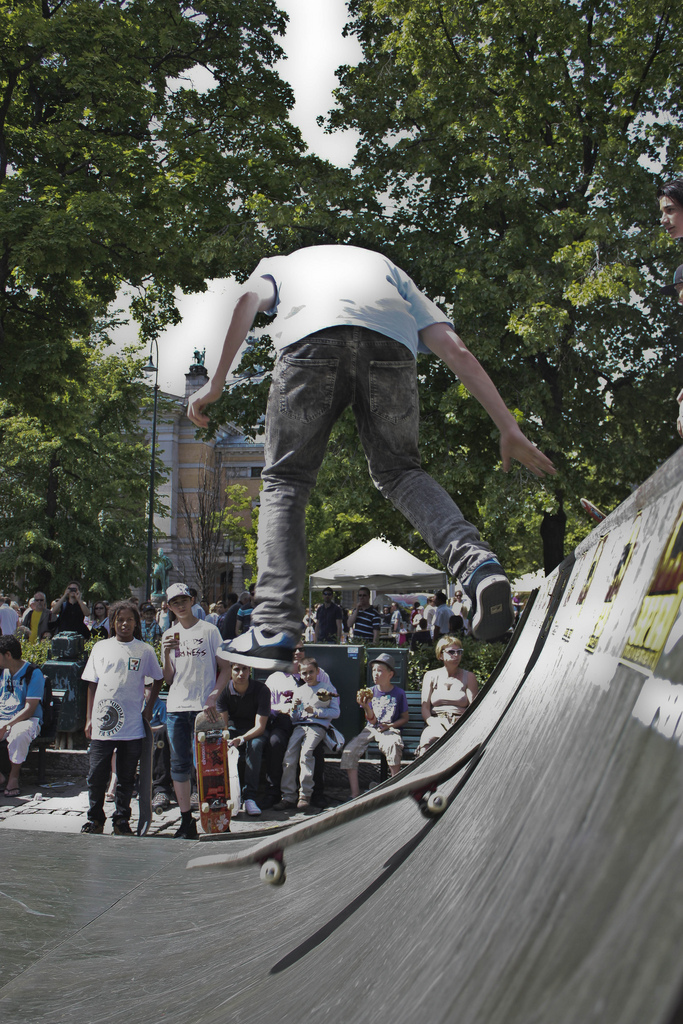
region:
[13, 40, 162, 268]
The tree branches have green leaves on them.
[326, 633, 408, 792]
A boy wearing a hat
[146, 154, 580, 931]
Skateboarder performing a stunt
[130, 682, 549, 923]
Skateboard photographed in motion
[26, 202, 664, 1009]
Boy skateboarding in half-pipe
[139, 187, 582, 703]
Airborne skateboarder with white shirt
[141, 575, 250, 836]
Boy with red skateboard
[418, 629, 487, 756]
Woman with sunglasses sitting on bench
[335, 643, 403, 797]
Boy with head eating sandwich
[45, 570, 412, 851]
People watching the skateboarder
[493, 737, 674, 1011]
Surface of skateboarding half-pipe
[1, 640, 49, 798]
Man in blue shirt sitting on bench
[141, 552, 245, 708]
Boy is wearing a hat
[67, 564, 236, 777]
Two guys have on white shirts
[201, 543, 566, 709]
Guy wearing black sneakers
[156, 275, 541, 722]
Guy has on black jeans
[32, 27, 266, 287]
Green leaves on a tree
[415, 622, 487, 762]
Woman has on sunglasses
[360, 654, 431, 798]
Boy is sitting on a bench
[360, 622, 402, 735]
Boy is wearing a hat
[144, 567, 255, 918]
Guy is holding a skateboard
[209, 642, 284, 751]
Guy has on a black shirt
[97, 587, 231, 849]
skateboarders are watching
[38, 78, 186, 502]
tall trees surround the park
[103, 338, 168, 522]
lamp post is nearby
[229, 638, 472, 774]
people sit on park benches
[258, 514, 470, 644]
tent canopy is erected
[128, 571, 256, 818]
boy in hat holds skateboard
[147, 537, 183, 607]
statue of a man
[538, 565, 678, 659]
ads are stuck to the ramp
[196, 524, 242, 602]
one tree has no leaves yet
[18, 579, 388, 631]
people are watching skateboarders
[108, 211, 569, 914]
Skateboarder suspended in mid-air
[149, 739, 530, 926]
A skateboard in motion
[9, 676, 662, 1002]
A skateboard on a half-pipte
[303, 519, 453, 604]
The top of a tent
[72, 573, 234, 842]
Two people with skateboards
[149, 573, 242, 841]
A boy with a skateboard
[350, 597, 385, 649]
A man in a striped shirt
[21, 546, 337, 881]
People watching a skateboarder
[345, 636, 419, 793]
A boy sitting on a bench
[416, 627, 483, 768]
A woman with sunglasses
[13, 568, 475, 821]
crowd gathered at a skate park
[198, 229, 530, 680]
skater is in the air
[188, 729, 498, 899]
skateboard is sliding down ramp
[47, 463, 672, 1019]
rubber half pipe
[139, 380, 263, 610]
building in the background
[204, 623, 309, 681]
left foot of skateboarder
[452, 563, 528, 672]
right foot of skateboarder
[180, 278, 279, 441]
left arm of skateboarder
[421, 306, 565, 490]
right arm of skateboarder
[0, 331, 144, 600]
trees in the background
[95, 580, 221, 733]
Two people have on white shirts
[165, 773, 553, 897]
A skateboard on a ramp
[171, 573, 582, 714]
Boy has on black sneakers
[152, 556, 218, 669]
Guy has a hat on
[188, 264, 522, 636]
Guy has on black faded jeans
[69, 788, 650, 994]
A ramp is black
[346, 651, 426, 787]
A boy is sitting on a bench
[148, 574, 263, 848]
Guys is holding a skateboard